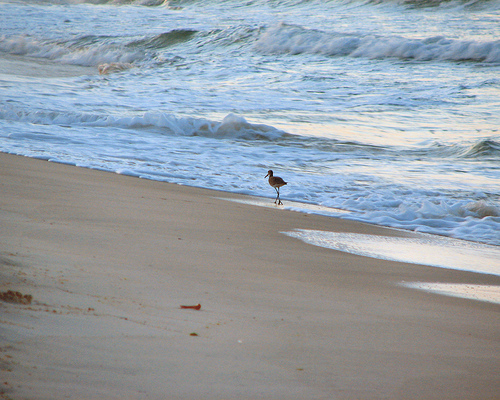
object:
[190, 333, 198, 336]
pebble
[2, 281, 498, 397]
sand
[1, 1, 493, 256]
ocean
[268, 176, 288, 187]
body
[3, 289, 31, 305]
clumps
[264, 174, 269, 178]
beak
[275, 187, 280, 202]
legs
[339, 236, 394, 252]
sand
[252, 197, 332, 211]
wet patch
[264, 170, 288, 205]
bird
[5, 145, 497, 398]
beach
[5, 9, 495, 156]
foamy wave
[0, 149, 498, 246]
shore line